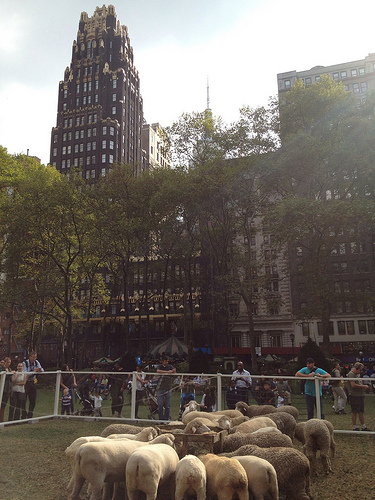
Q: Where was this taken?
A: City.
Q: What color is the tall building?
A: Black and gold.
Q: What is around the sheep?
A: Fence.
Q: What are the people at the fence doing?
A: Watching the sheep.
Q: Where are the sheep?
A: Fenced in pen.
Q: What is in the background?
A: Trees and buildings.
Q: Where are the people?
A: Outside the fence.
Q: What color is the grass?
A: Green.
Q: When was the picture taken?
A: Day time.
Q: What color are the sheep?
A: Tan.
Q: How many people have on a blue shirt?
A: One.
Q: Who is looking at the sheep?
A: Group of people.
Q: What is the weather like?
A: Sunny.